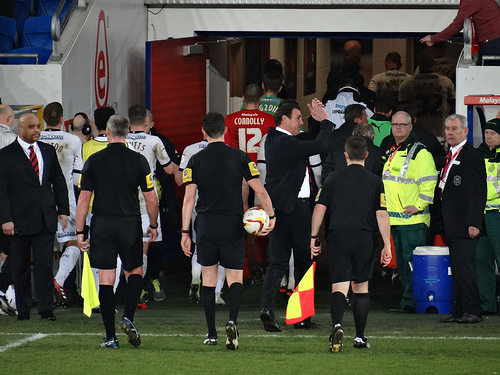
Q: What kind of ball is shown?
A: A soccer ball.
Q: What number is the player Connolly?
A: 12.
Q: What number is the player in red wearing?
A: 12.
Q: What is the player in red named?
A: Connolly.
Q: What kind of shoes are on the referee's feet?
A: Cleats.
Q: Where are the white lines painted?
A: On the field.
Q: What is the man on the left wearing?
A: A suit.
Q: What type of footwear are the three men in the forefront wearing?
A: Cleats.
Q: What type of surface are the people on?
A: Grass.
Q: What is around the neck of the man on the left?
A: A tie.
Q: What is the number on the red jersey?
A: 12.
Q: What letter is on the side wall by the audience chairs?
A: The letter e.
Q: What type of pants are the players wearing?
A: Shorts.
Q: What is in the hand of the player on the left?
A: A yellow towel.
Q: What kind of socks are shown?
A: Knee high socks.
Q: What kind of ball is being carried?
A: Soccerball.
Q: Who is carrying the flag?
A: Man on right.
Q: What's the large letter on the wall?
A: E.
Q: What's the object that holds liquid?
A: Cooler.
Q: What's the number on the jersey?
A: 12.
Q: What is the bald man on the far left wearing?
A: Suit.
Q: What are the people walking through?
A: Large doorway.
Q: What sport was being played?
A: Soccer.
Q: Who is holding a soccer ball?
A: The man in the middle.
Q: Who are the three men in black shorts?
A: Soccer referees.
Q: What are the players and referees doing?
A: Walking off the field.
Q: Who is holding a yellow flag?
A: The man in black shorts on the left.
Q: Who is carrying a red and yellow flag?
A: The man in shorts on the right.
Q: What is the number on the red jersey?
A: 12.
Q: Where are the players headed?
A: Into the tunnel.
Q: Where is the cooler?
A: On the ground near the man in the reflective vest.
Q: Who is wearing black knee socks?
A: The three men wearing black shorts.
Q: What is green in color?
A: The grass.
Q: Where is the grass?
A: Under the people.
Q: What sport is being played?
A: Soccer.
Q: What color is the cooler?
A: Blue.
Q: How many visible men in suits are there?
A: Three.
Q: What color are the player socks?
A: Black.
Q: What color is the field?
A: Green.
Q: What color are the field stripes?
A: White.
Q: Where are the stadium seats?
A: Upper left corner.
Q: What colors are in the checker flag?
A: Red and yellow.